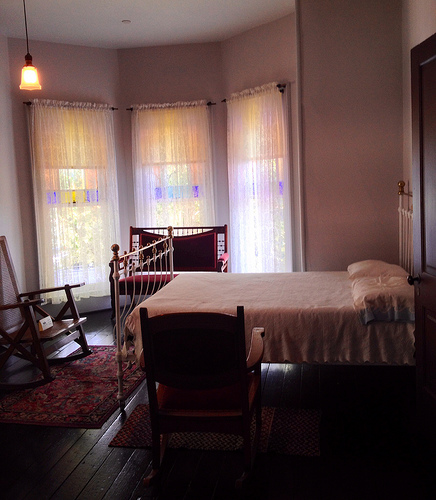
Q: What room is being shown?
A: Bedroom.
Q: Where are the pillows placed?
A: Bed.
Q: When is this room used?
A: Night time.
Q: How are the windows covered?
A: Drapes.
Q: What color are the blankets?
A: White.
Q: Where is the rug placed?
A: Floor.